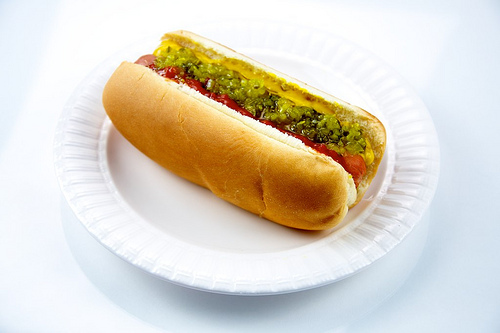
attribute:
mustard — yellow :
[150, 27, 260, 80]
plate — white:
[53, 45, 442, 297]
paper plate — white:
[47, 45, 453, 270]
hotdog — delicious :
[75, 15, 410, 239]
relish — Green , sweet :
[213, 59, 341, 150]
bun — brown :
[109, 20, 401, 244]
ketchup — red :
[158, 65, 343, 170]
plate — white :
[46, 31, 449, 306]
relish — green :
[157, 49, 367, 161]